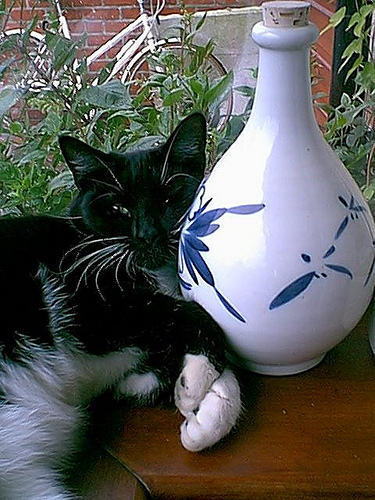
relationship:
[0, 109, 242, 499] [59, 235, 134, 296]
cat has whiskers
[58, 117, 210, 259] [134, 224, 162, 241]
cat has nose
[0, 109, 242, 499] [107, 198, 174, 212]
cat has eyes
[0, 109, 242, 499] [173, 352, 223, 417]
cat has claw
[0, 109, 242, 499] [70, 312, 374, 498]
cat lying on brown table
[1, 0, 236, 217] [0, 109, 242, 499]
plants behind cat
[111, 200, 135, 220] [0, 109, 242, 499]
eye of cat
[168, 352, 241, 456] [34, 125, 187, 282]
claw of cat